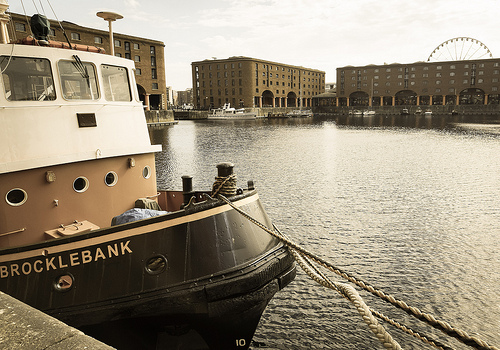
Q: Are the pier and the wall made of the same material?
A: Yes, both the pier and the wall are made of concrete.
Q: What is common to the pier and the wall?
A: The material, both the pier and the wall are concrete.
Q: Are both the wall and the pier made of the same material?
A: Yes, both the wall and the pier are made of concrete.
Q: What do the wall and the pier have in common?
A: The material, both the wall and the pier are concrete.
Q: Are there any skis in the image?
A: No, there are no skis.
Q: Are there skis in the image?
A: No, there are no skis.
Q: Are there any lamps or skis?
A: No, there are no skis or lamps.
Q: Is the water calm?
A: Yes, the water is calm.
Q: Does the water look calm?
A: Yes, the water is calm.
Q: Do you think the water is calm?
A: Yes, the water is calm.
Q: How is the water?
A: The water is calm.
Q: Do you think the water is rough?
A: No, the water is calm.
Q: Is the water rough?
A: No, the water is calm.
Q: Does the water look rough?
A: No, the water is calm.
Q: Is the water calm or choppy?
A: The water is calm.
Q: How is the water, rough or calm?
A: The water is calm.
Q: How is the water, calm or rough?
A: The water is calm.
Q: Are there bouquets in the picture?
A: No, there are no bouquets.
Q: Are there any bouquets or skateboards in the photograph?
A: No, there are no bouquets or skateboards.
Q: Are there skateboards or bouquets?
A: No, there are no bouquets or skateboards.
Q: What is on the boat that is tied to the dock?
A: The rope is on the boat.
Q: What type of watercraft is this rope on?
A: The rope is on the boat.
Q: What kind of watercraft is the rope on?
A: The rope is on the boat.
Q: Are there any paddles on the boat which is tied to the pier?
A: No, there is a rope on the boat.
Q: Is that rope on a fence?
A: No, the rope is on the boat.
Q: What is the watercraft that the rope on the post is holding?
A: The watercraft is a boat.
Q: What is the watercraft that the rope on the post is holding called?
A: The watercraft is a boat.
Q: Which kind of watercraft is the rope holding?
A: The rope is holding the boat.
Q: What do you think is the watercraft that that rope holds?
A: The watercraft is boats.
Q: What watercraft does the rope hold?
A: The rope holds the boats.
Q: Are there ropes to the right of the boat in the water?
A: Yes, there is a rope to the right of the boat.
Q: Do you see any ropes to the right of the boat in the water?
A: Yes, there is a rope to the right of the boat.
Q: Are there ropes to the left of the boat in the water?
A: No, the rope is to the right of the boat.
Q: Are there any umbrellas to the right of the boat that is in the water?
A: No, there is a rope to the right of the boat.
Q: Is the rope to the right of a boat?
A: Yes, the rope is to the right of a boat.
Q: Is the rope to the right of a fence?
A: No, the rope is to the right of a boat.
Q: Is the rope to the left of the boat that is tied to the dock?
A: No, the rope is to the right of the boat.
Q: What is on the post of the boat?
A: The rope is on the post.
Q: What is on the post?
A: The rope is on the post.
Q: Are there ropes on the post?
A: Yes, there is a rope on the post.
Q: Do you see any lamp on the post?
A: No, there is a rope on the post.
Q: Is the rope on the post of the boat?
A: Yes, the rope is on the post.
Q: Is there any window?
A: Yes, there are windows.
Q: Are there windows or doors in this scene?
A: Yes, there are windows.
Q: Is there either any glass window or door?
A: Yes, there are glass windows.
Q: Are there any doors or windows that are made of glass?
A: Yes, the windows are made of glass.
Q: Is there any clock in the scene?
A: No, there are no clocks.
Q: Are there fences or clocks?
A: No, there are no clocks or fences.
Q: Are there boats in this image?
A: Yes, there is a boat.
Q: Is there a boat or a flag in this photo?
A: Yes, there is a boat.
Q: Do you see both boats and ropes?
A: Yes, there are both a boat and a rope.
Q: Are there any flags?
A: No, there are no flags.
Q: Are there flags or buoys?
A: No, there are no flags or buoys.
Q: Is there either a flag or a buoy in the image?
A: No, there are no flags or buoys.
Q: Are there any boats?
A: Yes, there is a boat.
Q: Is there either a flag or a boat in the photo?
A: Yes, there is a boat.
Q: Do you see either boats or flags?
A: Yes, there is a boat.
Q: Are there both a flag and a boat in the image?
A: No, there is a boat but no flags.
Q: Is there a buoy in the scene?
A: No, there are no buoys.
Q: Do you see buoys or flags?
A: No, there are no buoys or flags.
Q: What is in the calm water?
A: The boat is in the water.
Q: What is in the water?
A: The boat is in the water.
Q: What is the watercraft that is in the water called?
A: The watercraft is a boat.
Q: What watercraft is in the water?
A: The watercraft is a boat.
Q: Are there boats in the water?
A: Yes, there is a boat in the water.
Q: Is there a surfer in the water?
A: No, there is a boat in the water.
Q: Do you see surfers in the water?
A: No, there is a boat in the water.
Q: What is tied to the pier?
A: The boat is tied to the pier.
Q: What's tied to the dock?
A: The boat is tied to the pier.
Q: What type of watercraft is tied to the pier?
A: The watercraft is a boat.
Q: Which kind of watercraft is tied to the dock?
A: The watercraft is a boat.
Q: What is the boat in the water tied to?
A: The boat is tied to the pier.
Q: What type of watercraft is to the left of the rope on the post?
A: The watercraft is a boat.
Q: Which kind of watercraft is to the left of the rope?
A: The watercraft is a boat.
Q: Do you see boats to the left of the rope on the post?
A: Yes, there is a boat to the left of the rope.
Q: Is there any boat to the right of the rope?
A: No, the boat is to the left of the rope.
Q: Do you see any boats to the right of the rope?
A: No, the boat is to the left of the rope.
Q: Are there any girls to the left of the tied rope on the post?
A: No, there is a boat to the left of the rope.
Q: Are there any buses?
A: No, there are no buses.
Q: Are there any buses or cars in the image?
A: No, there are no buses or cars.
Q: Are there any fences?
A: No, there are no fences.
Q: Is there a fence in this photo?
A: No, there are no fences.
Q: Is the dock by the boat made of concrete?
A: Yes, the pier is made of concrete.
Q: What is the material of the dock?
A: The dock is made of cement.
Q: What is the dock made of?
A: The dock is made of concrete.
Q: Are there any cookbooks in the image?
A: No, there are no cookbooks.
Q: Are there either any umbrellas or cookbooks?
A: No, there are no cookbooks or umbrellas.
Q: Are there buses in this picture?
A: No, there are no buses.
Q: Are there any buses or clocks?
A: No, there are no buses or clocks.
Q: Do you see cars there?
A: No, there are no cars.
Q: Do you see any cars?
A: No, there are no cars.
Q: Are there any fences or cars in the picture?
A: No, there are no cars or fences.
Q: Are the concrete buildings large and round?
A: No, the buildings are large but rectangular.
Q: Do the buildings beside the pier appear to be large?
A: Yes, the buildings are large.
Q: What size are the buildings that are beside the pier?
A: The buildings are large.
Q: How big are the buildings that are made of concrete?
A: The buildings are large.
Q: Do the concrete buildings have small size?
A: No, the buildings are large.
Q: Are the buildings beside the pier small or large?
A: The buildings are large.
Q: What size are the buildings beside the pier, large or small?
A: The buildings are large.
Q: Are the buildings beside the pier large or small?
A: The buildings are large.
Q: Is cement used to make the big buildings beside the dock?
A: Yes, the buildings are made of cement.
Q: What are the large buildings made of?
A: The buildings are made of concrete.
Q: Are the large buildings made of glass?
A: No, the buildings are made of concrete.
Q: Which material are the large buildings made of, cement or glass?
A: The buildings are made of cement.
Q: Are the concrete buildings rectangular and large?
A: Yes, the buildings are rectangular and large.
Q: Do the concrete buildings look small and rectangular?
A: No, the buildings are rectangular but large.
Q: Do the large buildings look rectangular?
A: Yes, the buildings are rectangular.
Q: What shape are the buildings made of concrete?
A: The buildings are rectangular.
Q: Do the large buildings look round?
A: No, the buildings are rectangular.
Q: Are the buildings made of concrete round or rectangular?
A: The buildings are rectangular.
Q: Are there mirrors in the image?
A: No, there are no mirrors.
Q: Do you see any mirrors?
A: No, there are no mirrors.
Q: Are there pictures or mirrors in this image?
A: No, there are no mirrors or pictures.